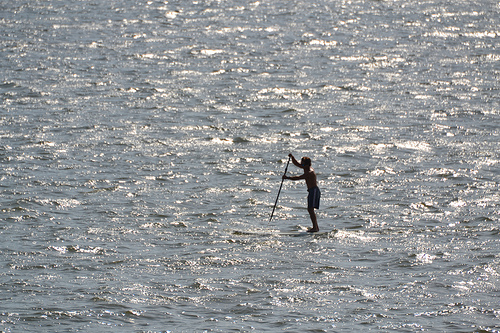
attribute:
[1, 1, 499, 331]
water — wavy, buoyant, reflective, rippling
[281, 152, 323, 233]
man — paddle boarding, shirtless, barefoot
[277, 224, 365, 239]
paddle board — floating, white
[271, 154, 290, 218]
paddle — black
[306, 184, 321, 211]
swimming trunks — blue, white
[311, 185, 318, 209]
stripe — white